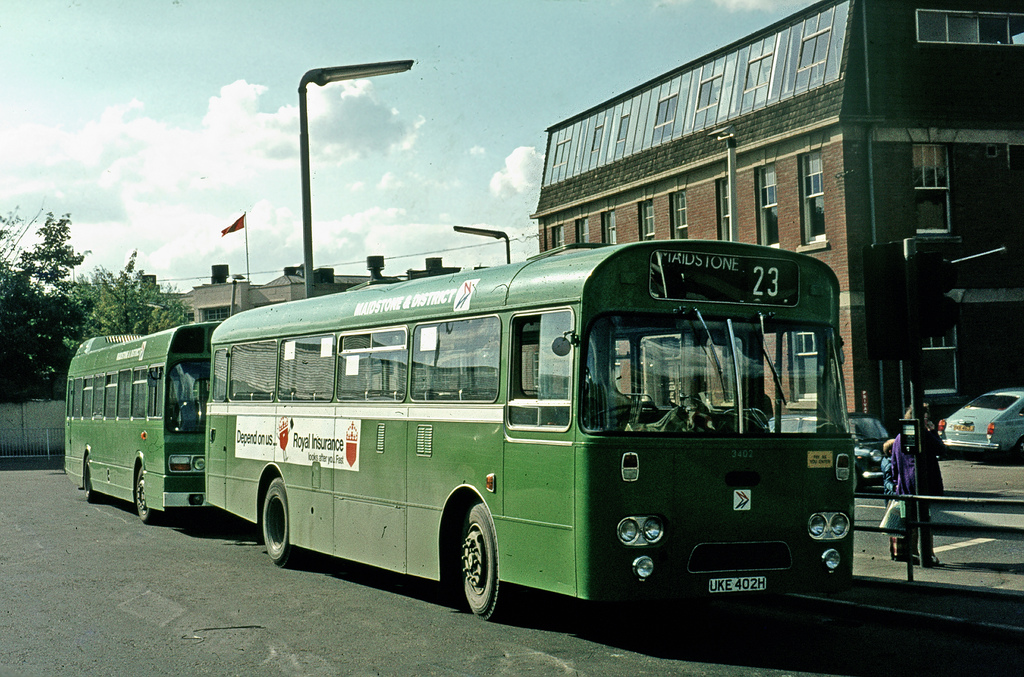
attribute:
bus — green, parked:
[203, 245, 861, 606]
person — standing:
[888, 398, 950, 567]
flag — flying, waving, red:
[220, 207, 257, 239]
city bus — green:
[70, 326, 204, 514]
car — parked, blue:
[951, 380, 1022, 454]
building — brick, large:
[587, 75, 1000, 244]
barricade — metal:
[8, 423, 57, 459]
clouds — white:
[184, 97, 284, 195]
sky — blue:
[95, 30, 294, 188]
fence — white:
[8, 399, 64, 424]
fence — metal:
[5, 431, 68, 463]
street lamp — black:
[295, 55, 416, 289]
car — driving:
[846, 415, 886, 489]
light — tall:
[309, 50, 420, 90]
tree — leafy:
[5, 237, 81, 372]